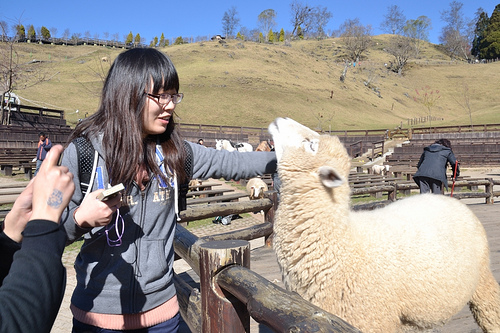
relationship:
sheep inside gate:
[262, 112, 498, 328] [182, 223, 350, 333]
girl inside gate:
[62, 43, 272, 333] [182, 223, 350, 333]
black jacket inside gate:
[0, 181, 99, 331] [182, 223, 350, 333]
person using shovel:
[413, 138, 459, 197] [451, 156, 463, 196]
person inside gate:
[413, 138, 459, 197] [182, 223, 350, 333]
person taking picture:
[0, 125, 61, 332] [84, 44, 351, 243]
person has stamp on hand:
[0, 125, 61, 332] [33, 145, 74, 225]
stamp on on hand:
[48, 186, 67, 212] [33, 145, 74, 225]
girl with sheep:
[62, 43, 272, 333] [262, 112, 498, 328]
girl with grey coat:
[62, 43, 272, 333] [44, 135, 215, 310]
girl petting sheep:
[62, 43, 272, 333] [262, 112, 498, 328]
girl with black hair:
[62, 43, 272, 333] [84, 41, 189, 197]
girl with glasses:
[70, 67, 201, 296] [146, 89, 190, 105]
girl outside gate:
[62, 43, 272, 333] [182, 223, 350, 333]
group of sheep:
[211, 124, 271, 198] [262, 112, 498, 328]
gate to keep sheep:
[182, 223, 350, 333] [262, 112, 498, 328]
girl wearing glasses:
[70, 67, 201, 296] [146, 89, 190, 105]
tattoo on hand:
[48, 186, 67, 212] [33, 145, 74, 225]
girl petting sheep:
[70, 67, 201, 296] [262, 112, 498, 328]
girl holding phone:
[62, 43, 272, 333] [92, 173, 129, 204]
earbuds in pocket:
[98, 208, 133, 246] [78, 203, 129, 291]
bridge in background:
[17, 23, 127, 51] [16, 18, 187, 98]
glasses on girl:
[146, 89, 190, 105] [62, 43, 272, 333]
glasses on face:
[146, 89, 190, 105] [133, 65, 186, 142]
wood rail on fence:
[226, 270, 318, 329] [154, 181, 329, 328]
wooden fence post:
[226, 270, 318, 329] [193, 226, 254, 332]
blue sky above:
[56, 3, 132, 23] [12, 1, 263, 61]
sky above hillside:
[89, 12, 197, 26] [29, 14, 423, 83]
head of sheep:
[266, 115, 354, 187] [262, 112, 498, 328]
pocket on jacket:
[78, 203, 129, 291] [44, 135, 215, 310]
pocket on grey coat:
[145, 235, 179, 280] [44, 127, 289, 310]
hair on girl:
[84, 41, 189, 197] [62, 43, 272, 333]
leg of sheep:
[473, 265, 498, 324] [262, 112, 498, 328]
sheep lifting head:
[262, 112, 498, 328] [266, 115, 354, 187]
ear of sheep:
[317, 164, 355, 194] [262, 112, 498, 328]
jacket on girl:
[44, 135, 215, 310] [62, 43, 272, 333]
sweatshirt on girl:
[44, 135, 215, 310] [62, 43, 272, 333]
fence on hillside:
[162, 224, 282, 330] [29, 14, 423, 83]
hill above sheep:
[179, 12, 383, 123] [262, 112, 498, 328]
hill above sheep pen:
[179, 12, 383, 123] [164, 94, 480, 289]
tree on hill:
[334, 18, 365, 75] [179, 12, 383, 123]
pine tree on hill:
[474, 9, 495, 71] [179, 12, 383, 123]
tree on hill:
[258, 7, 283, 37] [179, 12, 383, 123]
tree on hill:
[220, 4, 241, 42] [179, 12, 383, 123]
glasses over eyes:
[146, 89, 190, 105] [149, 81, 188, 121]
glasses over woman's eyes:
[146, 89, 190, 105] [89, 39, 193, 142]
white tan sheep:
[272, 127, 289, 140] [262, 112, 498, 328]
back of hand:
[33, 168, 65, 213] [33, 145, 74, 225]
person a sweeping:
[411, 134, 467, 186] [443, 141, 467, 196]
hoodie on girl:
[44, 135, 215, 310] [62, 43, 272, 333]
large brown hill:
[7, 13, 488, 118] [179, 12, 383, 123]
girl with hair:
[62, 43, 272, 333] [84, 41, 189, 197]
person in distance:
[411, 134, 467, 186] [371, 67, 464, 199]